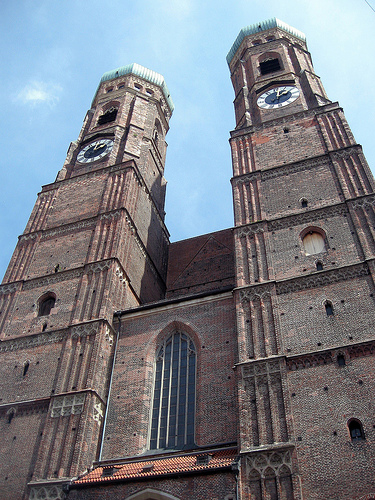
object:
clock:
[75, 138, 114, 164]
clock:
[256, 86, 300, 110]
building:
[1, 18, 374, 500]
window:
[144, 328, 200, 450]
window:
[38, 296, 55, 315]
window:
[348, 421, 364, 442]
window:
[336, 352, 346, 367]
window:
[324, 299, 335, 317]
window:
[316, 259, 324, 272]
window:
[300, 198, 309, 208]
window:
[283, 126, 290, 134]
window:
[256, 59, 284, 75]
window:
[7, 408, 15, 425]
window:
[22, 361, 30, 379]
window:
[40, 322, 50, 333]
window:
[53, 263, 61, 272]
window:
[96, 108, 118, 125]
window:
[153, 131, 161, 150]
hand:
[94, 140, 100, 151]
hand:
[96, 142, 108, 150]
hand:
[276, 86, 281, 96]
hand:
[278, 88, 291, 96]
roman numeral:
[257, 99, 265, 104]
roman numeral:
[261, 103, 267, 108]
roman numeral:
[267, 103, 274, 108]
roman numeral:
[77, 153, 85, 156]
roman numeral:
[79, 157, 85, 163]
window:
[105, 86, 114, 92]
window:
[119, 82, 127, 90]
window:
[134, 83, 143, 93]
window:
[266, 34, 276, 42]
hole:
[92, 412, 104, 426]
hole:
[93, 402, 105, 414]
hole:
[109, 334, 115, 346]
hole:
[104, 326, 110, 338]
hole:
[114, 268, 122, 276]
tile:
[72, 445, 241, 487]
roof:
[68, 445, 238, 486]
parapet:
[100, 62, 176, 117]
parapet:
[226, 16, 311, 61]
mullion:
[155, 340, 167, 451]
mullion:
[163, 334, 173, 450]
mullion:
[174, 332, 180, 448]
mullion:
[182, 337, 192, 447]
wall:
[98, 296, 238, 466]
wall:
[228, 34, 375, 500]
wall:
[163, 231, 235, 299]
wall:
[68, 469, 237, 499]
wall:
[1, 73, 165, 500]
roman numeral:
[278, 102, 283, 110]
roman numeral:
[286, 99, 293, 104]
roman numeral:
[289, 94, 302, 99]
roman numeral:
[89, 155, 97, 163]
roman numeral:
[98, 153, 103, 156]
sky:
[1, 1, 374, 283]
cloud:
[13, 77, 62, 117]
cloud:
[176, 186, 205, 233]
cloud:
[120, 1, 195, 65]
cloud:
[30, 6, 73, 83]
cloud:
[293, 2, 364, 40]